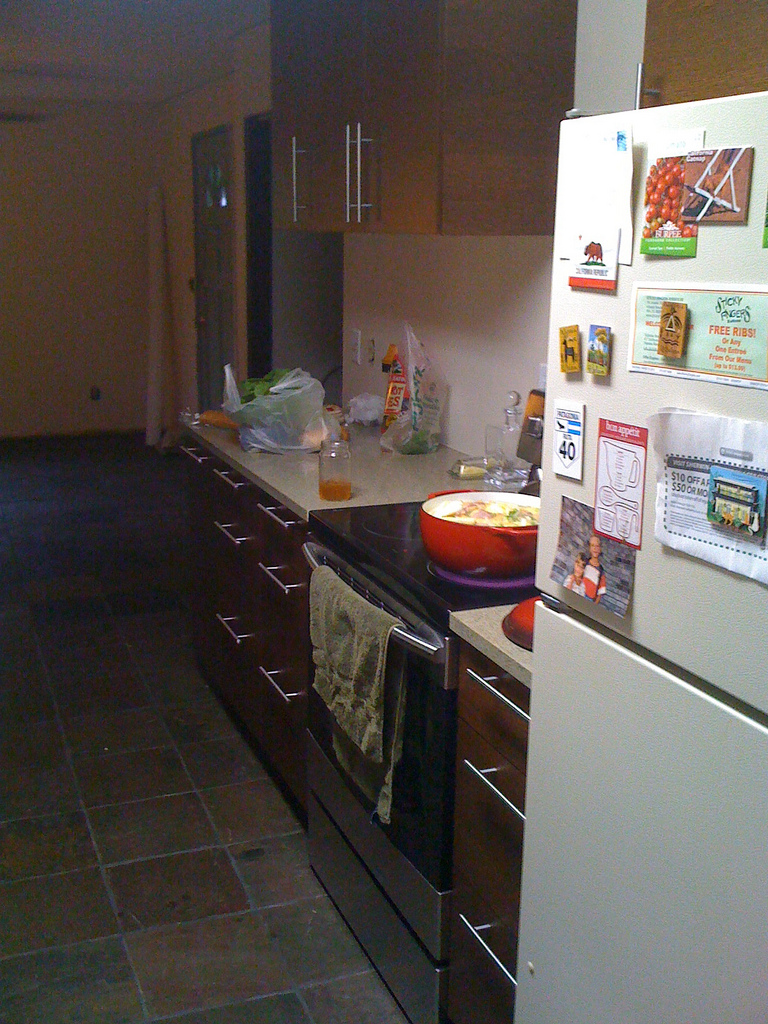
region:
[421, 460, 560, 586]
the pot is red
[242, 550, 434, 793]
the towel is hanging on the handle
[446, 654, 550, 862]
the drawers are brown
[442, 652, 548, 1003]
the drawers are made of wood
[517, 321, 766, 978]
the refrigerator is white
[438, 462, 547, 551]
the pot has food in it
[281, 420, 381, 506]
the jar has orange liquid in it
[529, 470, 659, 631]
a picture on the refrigerator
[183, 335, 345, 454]
a bag on top of the counter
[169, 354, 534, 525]
A messy counter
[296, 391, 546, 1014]
Stainless steel elective oven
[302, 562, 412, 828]
Green towel in the oven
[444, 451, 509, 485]
Butter in a glass container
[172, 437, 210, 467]
Stainless steel hardware on the cabinet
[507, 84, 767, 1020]
White refrigerator with magnets and paper on it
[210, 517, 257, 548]
Stainless steel hardware on the cabinet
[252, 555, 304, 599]
Stainless steel hardware on the cabinet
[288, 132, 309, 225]
Stainless steel hardware on the cabinet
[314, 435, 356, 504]
a clear glass jar on a counter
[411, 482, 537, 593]
a red bowl on a stove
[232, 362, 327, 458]
a plastic bag on a counter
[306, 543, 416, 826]
a towel hanging on a stove door handle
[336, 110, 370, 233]
silver handles on a cabinet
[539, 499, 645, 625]
a picture on a refrigerator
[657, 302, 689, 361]
a magnet on a refrigerator door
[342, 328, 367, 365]
a white light switch on a wall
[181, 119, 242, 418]
a wood door with a window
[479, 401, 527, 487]
a empty glass bottle on a counter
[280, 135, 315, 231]
Silver handle on cupboard.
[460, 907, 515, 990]
Silver handle on drawer.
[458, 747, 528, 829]
Silver handle on drawer.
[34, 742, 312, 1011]
Earth toned color tiles on ground.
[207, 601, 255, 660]
Silver handle on drawer.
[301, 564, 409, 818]
Green towel hanging from oven.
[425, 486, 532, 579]
Large red bowl sitting on stove.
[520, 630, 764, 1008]
Door on fridge is white.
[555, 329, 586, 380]
Yellow magnet with black dog.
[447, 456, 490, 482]
butter in container on counter top.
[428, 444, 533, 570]
a bowl ont he stove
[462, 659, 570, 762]
a silver drawer handle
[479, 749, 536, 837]
a silver drawer handle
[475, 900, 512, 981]
a silver drawer handle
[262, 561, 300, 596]
a silver drawer handle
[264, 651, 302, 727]
a silver drawer handle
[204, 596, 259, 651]
a silver drawer handle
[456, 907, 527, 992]
A handle for a drawer.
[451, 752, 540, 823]
A handle for a drawer.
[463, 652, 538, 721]
A handle for a drawer.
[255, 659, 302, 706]
A handle for a drawer.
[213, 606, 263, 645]
A handle for a drawer.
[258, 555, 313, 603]
A handle for a drawer.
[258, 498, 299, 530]
A handle for a drawer.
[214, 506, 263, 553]
A handle for a drawer.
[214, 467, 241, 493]
A handle for a drawer.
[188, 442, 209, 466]
A handle for a drawer.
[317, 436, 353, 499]
A mason jar on a table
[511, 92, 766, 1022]
A white refrigerator.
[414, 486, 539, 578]
A large orange pot.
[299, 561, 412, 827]
An olive green towel.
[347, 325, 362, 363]
A white outlet on a wall